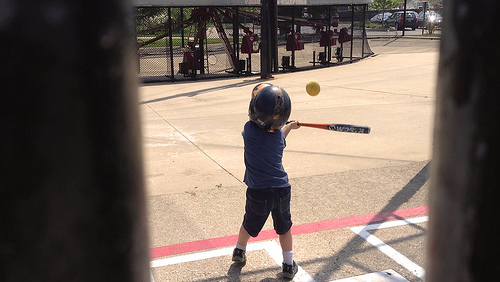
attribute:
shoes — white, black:
[227, 247, 308, 278]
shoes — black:
[262, 256, 319, 275]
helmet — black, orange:
[246, 80, 291, 133]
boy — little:
[218, 80, 303, 277]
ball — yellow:
[304, 76, 351, 126]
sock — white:
[281, 249, 293, 264]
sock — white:
[230, 237, 247, 252]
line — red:
[136, 200, 433, 272]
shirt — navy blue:
[213, 132, 302, 209]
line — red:
[143, 202, 428, 259]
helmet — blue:
[244, 81, 292, 128]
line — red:
[153, 200, 428, 262]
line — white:
[352, 224, 422, 275]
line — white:
[261, 237, 311, 280]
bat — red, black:
[287, 117, 374, 137]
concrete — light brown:
[136, 37, 441, 278]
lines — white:
[173, 233, 356, 280]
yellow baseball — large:
[291, 82, 336, 117]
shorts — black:
[243, 187, 298, 234]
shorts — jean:
[239, 176, 292, 238]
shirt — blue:
[244, 118, 291, 185]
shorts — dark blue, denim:
[203, 162, 345, 238]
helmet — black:
[248, 81, 292, 126]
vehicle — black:
[381, 10, 421, 30]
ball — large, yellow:
[304, 77, 321, 95]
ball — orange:
[301, 72, 324, 99]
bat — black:
[285, 103, 380, 146]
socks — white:
[282, 246, 307, 276]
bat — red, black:
[289, 110, 377, 148]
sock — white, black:
[279, 245, 299, 280]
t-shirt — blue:
[238, 119, 290, 189]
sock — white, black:
[215, 250, 251, 273]